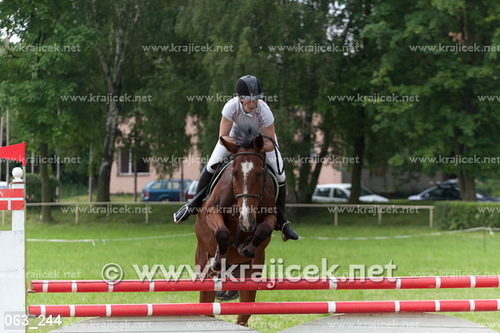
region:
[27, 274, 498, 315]
red and white jumping rails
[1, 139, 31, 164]
red flag on post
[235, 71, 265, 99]
helmet on rider's head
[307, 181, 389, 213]
white vehicle behind rider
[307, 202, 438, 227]
wooden rail fence in background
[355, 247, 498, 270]
green grass in field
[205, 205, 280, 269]
front hooves up to jump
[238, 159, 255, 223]
star on horse head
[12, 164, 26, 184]
round knob on fence post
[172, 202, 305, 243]
feet in stirrups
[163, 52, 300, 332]
person riding on a horse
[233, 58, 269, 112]
black helmet on a jockey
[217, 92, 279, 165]
white shirt on a jockey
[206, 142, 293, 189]
white pants on a jockey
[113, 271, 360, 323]
red and white poles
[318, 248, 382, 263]
short green grass in a field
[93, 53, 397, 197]
trees lining a street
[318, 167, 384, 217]
white car on a street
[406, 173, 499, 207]
car parked on a street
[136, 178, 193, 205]
blue car parked on a street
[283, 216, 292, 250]
part of a boot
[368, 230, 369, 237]
part of a garden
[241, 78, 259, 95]
part of a helmet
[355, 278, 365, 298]
part of a wall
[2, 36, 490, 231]
Copyrights in the image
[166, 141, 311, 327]
Horse is jumping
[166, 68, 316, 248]
This person is riding a horse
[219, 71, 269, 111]
Helmet is black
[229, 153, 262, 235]
White fur on the horse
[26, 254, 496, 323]
Gate is red and white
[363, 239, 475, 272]
Grass is short and green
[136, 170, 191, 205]
Car is blue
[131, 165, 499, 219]
Cars are parked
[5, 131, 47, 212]
A red flag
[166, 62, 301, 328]
person riding a horse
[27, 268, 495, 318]
obstacle for horse to jump over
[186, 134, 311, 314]
horse with person on it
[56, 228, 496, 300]
a field of grass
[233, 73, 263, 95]
helmet on horse rider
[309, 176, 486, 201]
vehicles on the road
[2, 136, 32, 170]
flag on the field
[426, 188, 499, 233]
bushes or shrubs on ground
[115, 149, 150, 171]
window to a building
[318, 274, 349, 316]
white marks on obstacle